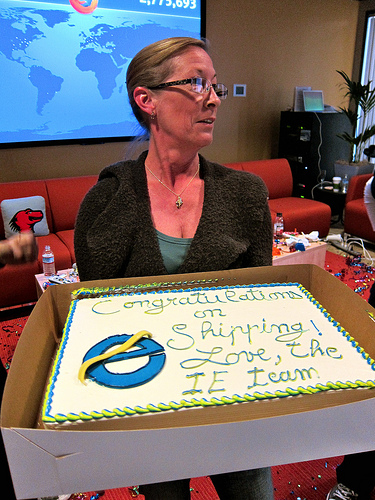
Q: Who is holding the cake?
A: A woman.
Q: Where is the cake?
A: In the box.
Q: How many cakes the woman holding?
A: One.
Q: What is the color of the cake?
A: White, blue, and yellow.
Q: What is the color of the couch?
A: Red.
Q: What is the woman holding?
A: A cake.